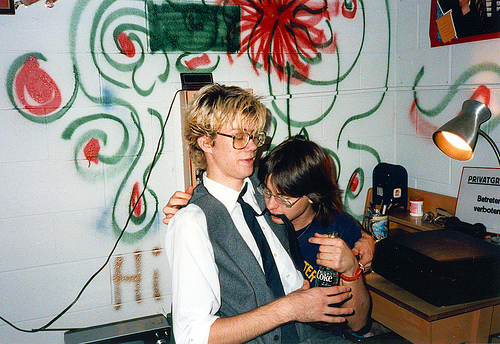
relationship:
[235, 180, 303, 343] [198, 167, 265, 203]
blue tie on neck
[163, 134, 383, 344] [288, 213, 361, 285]
lady wearing shirt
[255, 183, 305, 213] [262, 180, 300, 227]
eyeglasses on woman's face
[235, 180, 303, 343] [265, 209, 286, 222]
blue tie in mouth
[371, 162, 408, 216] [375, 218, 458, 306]
container on desk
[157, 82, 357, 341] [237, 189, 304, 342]
man has blue tie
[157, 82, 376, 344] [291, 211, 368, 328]
man has shirt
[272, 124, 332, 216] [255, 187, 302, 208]
man has eyeglasses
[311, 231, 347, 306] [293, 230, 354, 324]
bottle in hands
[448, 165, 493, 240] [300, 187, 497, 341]
sign on table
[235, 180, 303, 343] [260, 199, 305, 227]
blue tie in mouth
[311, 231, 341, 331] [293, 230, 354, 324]
bottle in hands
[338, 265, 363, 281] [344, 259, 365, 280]
watch on wrist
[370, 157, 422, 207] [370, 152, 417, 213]
container shaped like mailbox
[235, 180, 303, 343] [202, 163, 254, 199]
blue tie around neck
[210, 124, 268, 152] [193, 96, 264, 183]
eyeglasses on face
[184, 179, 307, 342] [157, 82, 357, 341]
grey vest on man